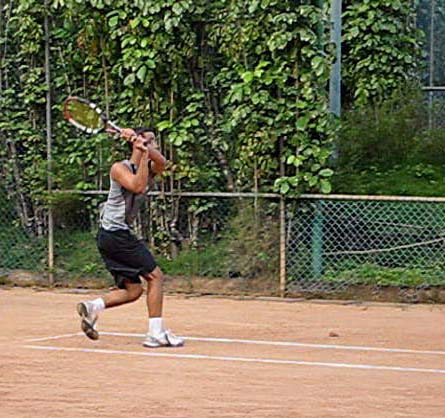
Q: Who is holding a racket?
A: A man.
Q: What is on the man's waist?
A: Shorts.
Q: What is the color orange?
A: The tennis court.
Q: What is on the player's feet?
A: Shoes.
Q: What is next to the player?
A: Tres.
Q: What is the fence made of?
A: Metal.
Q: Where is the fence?
A: Next to the man.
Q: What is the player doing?
A: Swinging.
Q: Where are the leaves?
A: On the tree.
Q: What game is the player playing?
A: Tennis.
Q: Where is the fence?
A: Behind the player.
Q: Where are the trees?
A: Behind the fence.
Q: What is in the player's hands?
A: A tennis racket.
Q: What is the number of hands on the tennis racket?
A: Two.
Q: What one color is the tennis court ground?
A: Brown.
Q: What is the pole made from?
A: Metal.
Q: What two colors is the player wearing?
A: Black and grey.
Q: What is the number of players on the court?
A: One.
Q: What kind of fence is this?
A: Chain link fence.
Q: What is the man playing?
A: Tennis.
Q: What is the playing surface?
A: Clay.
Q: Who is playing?
A: A man.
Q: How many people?
A: One.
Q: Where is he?
A: Tennis court.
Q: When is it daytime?
A: Now.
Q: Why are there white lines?
A: Boundary.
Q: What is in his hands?
A: Racquet.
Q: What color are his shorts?
A: Black.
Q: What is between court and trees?
A: Fence.